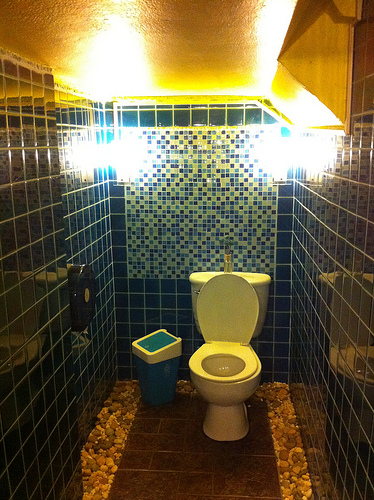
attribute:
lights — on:
[78, 123, 344, 186]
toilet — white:
[180, 262, 274, 446]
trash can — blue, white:
[125, 321, 189, 415]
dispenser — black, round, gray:
[64, 253, 96, 348]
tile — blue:
[119, 278, 187, 318]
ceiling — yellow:
[4, 6, 353, 130]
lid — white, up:
[193, 272, 263, 347]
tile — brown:
[111, 441, 273, 493]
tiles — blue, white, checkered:
[119, 126, 275, 277]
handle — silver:
[191, 286, 207, 300]